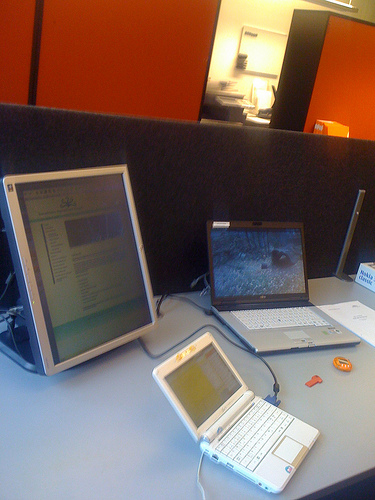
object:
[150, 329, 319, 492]
computer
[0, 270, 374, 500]
table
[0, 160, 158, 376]
computer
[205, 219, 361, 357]
computer